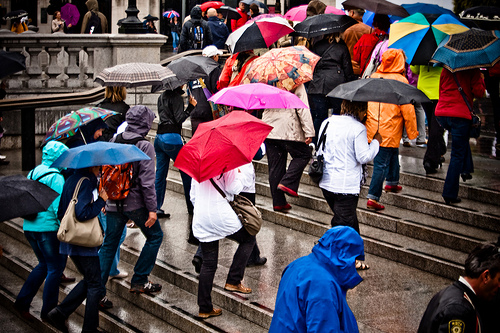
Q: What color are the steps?
A: Gray.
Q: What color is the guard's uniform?
A: Black.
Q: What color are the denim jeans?
A: Blue.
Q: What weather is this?
A: Rainy.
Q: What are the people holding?
A: Umbrellas.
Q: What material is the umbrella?
A: Fabric.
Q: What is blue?
A: Jacket.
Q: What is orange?
A: Raincoat.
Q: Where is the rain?
A: On the people.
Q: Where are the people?
A: On the stairs.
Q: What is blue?
A: Jacket.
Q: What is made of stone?
A: Stairs.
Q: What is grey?
A: Stairs.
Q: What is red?
A: Umbrella.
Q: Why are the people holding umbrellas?
A: Raining.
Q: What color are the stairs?
A: Brown.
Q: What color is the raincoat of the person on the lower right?
A: Blue.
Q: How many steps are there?
A: 8.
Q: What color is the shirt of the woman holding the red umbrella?
A: White.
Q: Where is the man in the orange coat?
A: On the stairs.